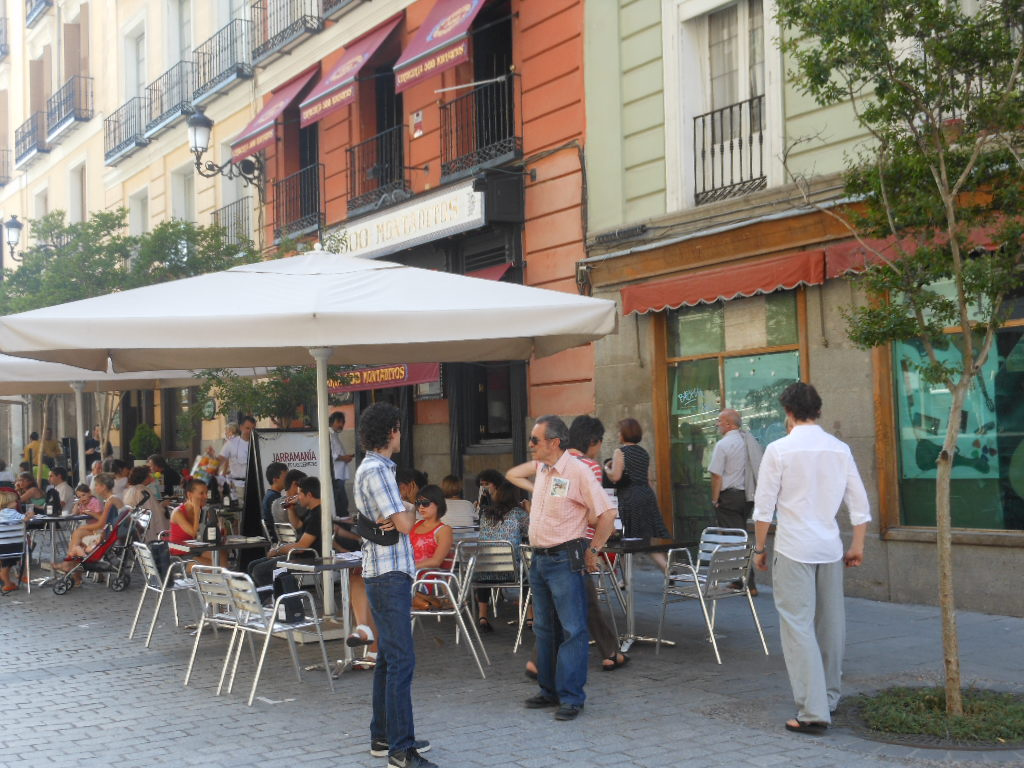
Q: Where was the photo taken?
A: Outdoor seating.